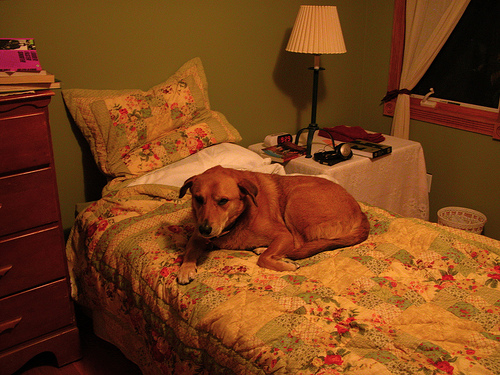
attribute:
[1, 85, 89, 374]
chest — brown 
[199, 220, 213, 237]
nose — black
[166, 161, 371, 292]
dog — Brown , laying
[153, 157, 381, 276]
dog — brown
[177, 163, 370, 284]
dog — brown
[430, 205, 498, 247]
trashcan — white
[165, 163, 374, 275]
dog — brown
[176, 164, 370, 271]
dog — laying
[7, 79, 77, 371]
dresser — wooden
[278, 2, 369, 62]
shade — white